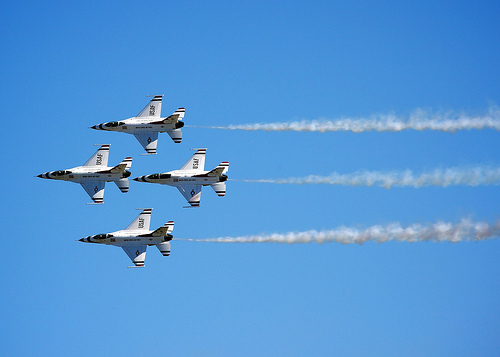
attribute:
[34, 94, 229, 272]
jets — f16s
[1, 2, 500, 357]
sky — blue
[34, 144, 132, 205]
jet — white